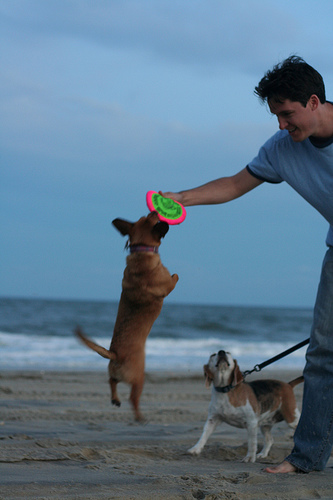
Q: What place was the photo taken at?
A: It was taken at the beach.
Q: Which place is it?
A: It is a beach.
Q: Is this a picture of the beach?
A: Yes, it is showing the beach.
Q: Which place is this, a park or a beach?
A: It is a beach.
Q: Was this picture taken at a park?
A: No, the picture was taken in a beach.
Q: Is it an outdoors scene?
A: Yes, it is outdoors.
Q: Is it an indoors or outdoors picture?
A: It is outdoors.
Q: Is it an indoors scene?
A: No, it is outdoors.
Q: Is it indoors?
A: No, it is outdoors.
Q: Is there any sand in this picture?
A: Yes, there is sand.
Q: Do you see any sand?
A: Yes, there is sand.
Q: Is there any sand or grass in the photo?
A: Yes, there is sand.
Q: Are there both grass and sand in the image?
A: No, there is sand but no grass.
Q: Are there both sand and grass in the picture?
A: No, there is sand but no grass.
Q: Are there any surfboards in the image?
A: No, there are no surfboards.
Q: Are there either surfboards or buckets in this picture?
A: No, there are no surfboards or buckets.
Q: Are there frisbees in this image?
A: Yes, there is a frisbee.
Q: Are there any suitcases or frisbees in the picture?
A: Yes, there is a frisbee.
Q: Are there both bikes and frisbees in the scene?
A: No, there is a frisbee but no bikes.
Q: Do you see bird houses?
A: No, there are no bird houses.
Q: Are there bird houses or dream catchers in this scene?
A: No, there are no bird houses or dream catchers.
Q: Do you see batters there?
A: No, there are no batters.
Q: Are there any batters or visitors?
A: No, there are no batters or visitors.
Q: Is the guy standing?
A: Yes, the guy is standing.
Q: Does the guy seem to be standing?
A: Yes, the guy is standing.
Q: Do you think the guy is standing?
A: Yes, the guy is standing.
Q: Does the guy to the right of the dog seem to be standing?
A: Yes, the guy is standing.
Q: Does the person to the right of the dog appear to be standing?
A: Yes, the guy is standing.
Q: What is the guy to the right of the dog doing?
A: The guy is standing.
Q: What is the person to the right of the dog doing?
A: The guy is standing.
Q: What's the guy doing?
A: The guy is standing.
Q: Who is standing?
A: The guy is standing.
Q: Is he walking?
A: No, the guy is standing.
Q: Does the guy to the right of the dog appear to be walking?
A: No, the guy is standing.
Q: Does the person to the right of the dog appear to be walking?
A: No, the guy is standing.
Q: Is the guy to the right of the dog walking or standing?
A: The guy is standing.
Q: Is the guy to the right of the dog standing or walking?
A: The guy is standing.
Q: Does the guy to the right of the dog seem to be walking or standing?
A: The guy is standing.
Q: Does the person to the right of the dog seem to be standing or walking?
A: The guy is standing.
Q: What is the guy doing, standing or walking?
A: The guy is standing.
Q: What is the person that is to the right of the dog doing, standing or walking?
A: The guy is standing.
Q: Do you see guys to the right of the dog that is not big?
A: Yes, there is a guy to the right of the dog.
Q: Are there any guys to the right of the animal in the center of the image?
A: Yes, there is a guy to the right of the dog.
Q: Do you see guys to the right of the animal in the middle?
A: Yes, there is a guy to the right of the dog.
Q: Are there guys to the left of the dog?
A: No, the guy is to the right of the dog.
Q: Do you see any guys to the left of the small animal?
A: No, the guy is to the right of the dog.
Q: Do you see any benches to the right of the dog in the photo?
A: No, there is a guy to the right of the dog.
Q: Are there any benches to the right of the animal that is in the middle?
A: No, there is a guy to the right of the dog.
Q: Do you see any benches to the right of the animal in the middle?
A: No, there is a guy to the right of the dog.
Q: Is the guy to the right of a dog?
A: Yes, the guy is to the right of a dog.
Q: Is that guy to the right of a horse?
A: No, the guy is to the right of a dog.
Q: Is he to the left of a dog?
A: No, the guy is to the right of a dog.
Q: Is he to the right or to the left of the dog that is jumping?
A: The guy is to the right of the dog.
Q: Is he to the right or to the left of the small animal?
A: The guy is to the right of the dog.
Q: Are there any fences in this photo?
A: No, there are no fences.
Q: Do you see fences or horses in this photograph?
A: No, there are no fences or horses.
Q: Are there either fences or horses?
A: No, there are no fences or horses.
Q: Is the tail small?
A: Yes, the tail is small.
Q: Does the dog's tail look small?
A: Yes, the tail is small.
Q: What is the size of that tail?
A: The tail is small.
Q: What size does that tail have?
A: The tail has small size.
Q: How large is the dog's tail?
A: The tail is small.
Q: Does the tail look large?
A: No, the tail is small.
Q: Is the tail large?
A: No, the tail is small.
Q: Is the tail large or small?
A: The tail is small.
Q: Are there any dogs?
A: Yes, there is a dog.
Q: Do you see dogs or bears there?
A: Yes, there is a dog.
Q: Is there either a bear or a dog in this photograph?
A: Yes, there is a dog.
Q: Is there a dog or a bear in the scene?
A: Yes, there is a dog.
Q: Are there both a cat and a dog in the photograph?
A: No, there is a dog but no cats.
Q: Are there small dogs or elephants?
A: Yes, there is a small dog.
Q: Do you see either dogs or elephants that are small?
A: Yes, the dog is small.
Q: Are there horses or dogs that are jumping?
A: Yes, the dog is jumping.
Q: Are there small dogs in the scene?
A: Yes, there is a small dog.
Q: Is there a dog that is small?
A: Yes, there is a small dog.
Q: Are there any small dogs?
A: Yes, there is a small dog.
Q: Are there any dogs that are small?
A: Yes, there is a dog that is small.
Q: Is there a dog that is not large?
A: Yes, there is a small dog.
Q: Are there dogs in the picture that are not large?
A: Yes, there is a small dog.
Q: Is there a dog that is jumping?
A: Yes, there is a dog that is jumping.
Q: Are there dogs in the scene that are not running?
A: Yes, there is a dog that is jumping.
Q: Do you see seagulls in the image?
A: No, there are no seagulls.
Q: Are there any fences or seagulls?
A: No, there are no seagulls or fences.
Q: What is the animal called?
A: The animal is a dog.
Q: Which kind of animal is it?
A: The animal is a dog.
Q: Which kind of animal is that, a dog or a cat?
A: That is a dog.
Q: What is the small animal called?
A: The animal is a dog.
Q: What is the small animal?
A: The animal is a dog.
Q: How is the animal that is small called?
A: The animal is a dog.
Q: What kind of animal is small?
A: The animal is a dog.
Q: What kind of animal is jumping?
A: The animal is a dog.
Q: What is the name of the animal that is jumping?
A: The animal is a dog.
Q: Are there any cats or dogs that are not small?
A: No, there is a dog but it is small.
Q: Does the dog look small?
A: Yes, the dog is small.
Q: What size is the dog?
A: The dog is small.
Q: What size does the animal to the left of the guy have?
A: The dog has small size.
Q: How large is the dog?
A: The dog is small.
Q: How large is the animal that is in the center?
A: The dog is small.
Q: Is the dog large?
A: No, the dog is small.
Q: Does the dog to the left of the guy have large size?
A: No, the dog is small.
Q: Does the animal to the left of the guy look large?
A: No, the dog is small.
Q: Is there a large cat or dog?
A: No, there is a dog but it is small.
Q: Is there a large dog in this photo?
A: No, there is a dog but it is small.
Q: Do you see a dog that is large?
A: No, there is a dog but it is small.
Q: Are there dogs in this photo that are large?
A: No, there is a dog but it is small.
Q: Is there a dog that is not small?
A: No, there is a dog but it is small.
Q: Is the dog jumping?
A: Yes, the dog is jumping.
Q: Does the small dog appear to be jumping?
A: Yes, the dog is jumping.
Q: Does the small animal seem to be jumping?
A: Yes, the dog is jumping.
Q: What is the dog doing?
A: The dog is jumping.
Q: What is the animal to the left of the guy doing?
A: The dog is jumping.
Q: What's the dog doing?
A: The dog is jumping.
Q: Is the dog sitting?
A: No, the dog is jumping.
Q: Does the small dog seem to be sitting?
A: No, the dog is jumping.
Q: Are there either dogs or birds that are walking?
A: No, there is a dog but it is jumping.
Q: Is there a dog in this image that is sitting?
A: No, there is a dog but it is jumping.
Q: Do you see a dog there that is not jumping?
A: No, there is a dog but it is jumping.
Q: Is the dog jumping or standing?
A: The dog is jumping.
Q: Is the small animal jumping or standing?
A: The dog is jumping.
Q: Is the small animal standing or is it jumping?
A: The dog is jumping.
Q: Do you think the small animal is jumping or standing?
A: The dog is jumping.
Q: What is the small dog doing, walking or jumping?
A: The dog is jumping.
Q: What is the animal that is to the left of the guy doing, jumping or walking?
A: The dog is jumping.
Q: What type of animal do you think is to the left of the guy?
A: The animal is a dog.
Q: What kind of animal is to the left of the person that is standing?
A: The animal is a dog.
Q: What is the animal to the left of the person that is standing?
A: The animal is a dog.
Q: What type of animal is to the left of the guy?
A: The animal is a dog.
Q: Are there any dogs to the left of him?
A: Yes, there is a dog to the left of the guy.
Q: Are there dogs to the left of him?
A: Yes, there is a dog to the left of the guy.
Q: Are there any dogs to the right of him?
A: No, the dog is to the left of the guy.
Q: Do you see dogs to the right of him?
A: No, the dog is to the left of the guy.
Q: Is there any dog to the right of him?
A: No, the dog is to the left of the guy.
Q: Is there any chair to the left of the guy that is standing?
A: No, there is a dog to the left of the guy.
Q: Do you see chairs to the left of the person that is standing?
A: No, there is a dog to the left of the guy.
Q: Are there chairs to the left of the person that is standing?
A: No, there is a dog to the left of the guy.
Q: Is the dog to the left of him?
A: Yes, the dog is to the left of the guy.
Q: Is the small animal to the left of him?
A: Yes, the dog is to the left of the guy.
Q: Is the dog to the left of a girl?
A: No, the dog is to the left of the guy.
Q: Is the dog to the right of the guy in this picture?
A: No, the dog is to the left of the guy.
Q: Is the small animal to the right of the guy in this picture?
A: No, the dog is to the left of the guy.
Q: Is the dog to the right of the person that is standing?
A: No, the dog is to the left of the guy.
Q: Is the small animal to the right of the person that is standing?
A: No, the dog is to the left of the guy.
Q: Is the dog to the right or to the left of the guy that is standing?
A: The dog is to the left of the guy.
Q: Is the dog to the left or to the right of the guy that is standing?
A: The dog is to the left of the guy.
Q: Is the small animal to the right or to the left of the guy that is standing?
A: The dog is to the left of the guy.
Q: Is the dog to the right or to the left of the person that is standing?
A: The dog is to the left of the guy.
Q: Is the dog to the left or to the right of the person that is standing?
A: The dog is to the left of the guy.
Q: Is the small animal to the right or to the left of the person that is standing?
A: The dog is to the left of the guy.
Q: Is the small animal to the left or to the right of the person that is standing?
A: The dog is to the left of the guy.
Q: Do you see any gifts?
A: No, there are no gifts.